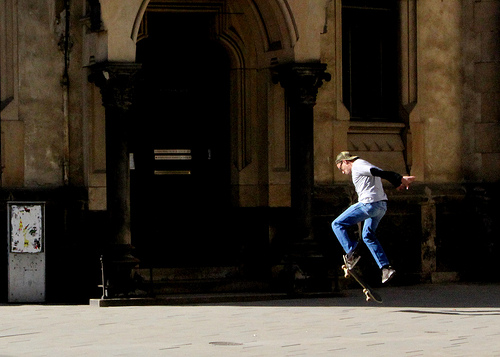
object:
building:
[0, 1, 499, 305]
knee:
[327, 217, 349, 230]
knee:
[359, 229, 374, 241]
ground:
[0, 279, 499, 356]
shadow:
[390, 303, 499, 317]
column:
[267, 60, 330, 291]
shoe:
[379, 266, 399, 284]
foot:
[377, 265, 394, 285]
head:
[332, 149, 350, 178]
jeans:
[329, 200, 390, 271]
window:
[338, 0, 406, 123]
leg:
[358, 219, 388, 268]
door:
[124, 30, 234, 262]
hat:
[331, 150, 359, 163]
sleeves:
[368, 166, 403, 185]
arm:
[355, 158, 401, 188]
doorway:
[118, 25, 258, 285]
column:
[86, 60, 142, 298]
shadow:
[97, 278, 499, 308]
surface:
[0, 284, 499, 356]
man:
[327, 150, 413, 286]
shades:
[335, 160, 344, 176]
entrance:
[130, 36, 238, 267]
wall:
[410, 0, 498, 184]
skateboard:
[339, 262, 384, 305]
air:
[166, 304, 441, 343]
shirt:
[348, 156, 388, 205]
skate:
[326, 147, 417, 305]